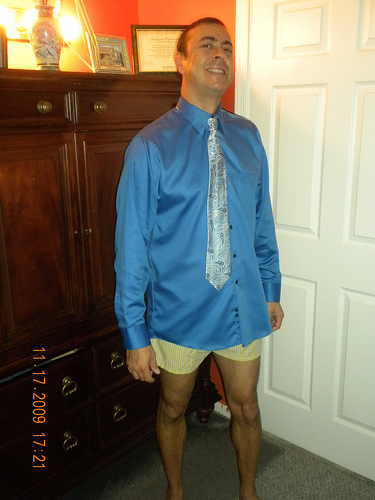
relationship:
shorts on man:
[153, 337, 261, 374] [149, 50, 295, 445]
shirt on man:
[113, 95, 280, 350] [112, 25, 284, 372]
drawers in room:
[3, 332, 216, 491] [11, 16, 364, 472]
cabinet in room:
[12, 130, 98, 323] [11, 16, 364, 472]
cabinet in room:
[73, 123, 168, 296] [11, 16, 364, 472]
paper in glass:
[127, 23, 209, 73] [140, 33, 183, 68]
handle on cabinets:
[54, 369, 87, 401] [0, 346, 92, 448]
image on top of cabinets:
[84, 32, 135, 72] [2, 66, 223, 494]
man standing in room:
[113, 17, 285, 500] [0, 0, 373, 499]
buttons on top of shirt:
[212, 211, 263, 298] [153, 134, 289, 300]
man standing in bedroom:
[113, 15, 374, 385] [4, 3, 371, 495]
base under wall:
[214, 402, 232, 419] [83, 0, 234, 77]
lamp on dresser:
[28, 1, 64, 71] [2, 60, 187, 321]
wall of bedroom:
[81, 1, 234, 71] [1, 6, 236, 115]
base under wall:
[215, 402, 234, 422] [210, 364, 223, 387]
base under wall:
[214, 402, 232, 419] [133, 1, 243, 426]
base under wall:
[214, 402, 232, 419] [208, 362, 229, 407]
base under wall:
[214, 402, 232, 419] [1, 1, 236, 408]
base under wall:
[214, 402, 232, 419] [99, 2, 225, 15]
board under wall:
[11, 40, 98, 71] [2, 0, 137, 68]